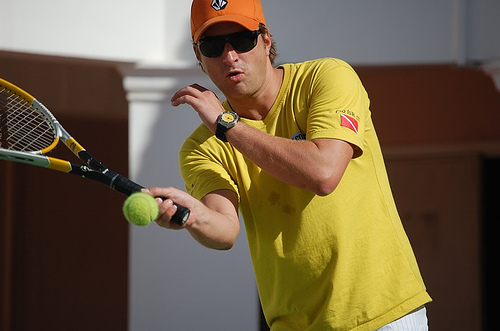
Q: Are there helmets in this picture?
A: No, there are no helmets.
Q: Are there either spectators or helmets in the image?
A: No, there are no helmets or spectators.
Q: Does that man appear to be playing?
A: Yes, the man is playing.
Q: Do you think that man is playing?
A: Yes, the man is playing.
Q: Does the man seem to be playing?
A: Yes, the man is playing.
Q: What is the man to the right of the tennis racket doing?
A: The man is playing.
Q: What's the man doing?
A: The man is playing.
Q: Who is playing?
A: The man is playing.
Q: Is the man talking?
A: No, the man is playing.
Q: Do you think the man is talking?
A: No, the man is playing.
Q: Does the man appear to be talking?
A: No, the man is playing.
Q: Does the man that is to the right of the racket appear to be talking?
A: No, the man is playing.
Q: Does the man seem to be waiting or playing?
A: The man is playing.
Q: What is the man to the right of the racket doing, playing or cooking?
A: The man is playing.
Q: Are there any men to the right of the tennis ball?
A: Yes, there is a man to the right of the tennis ball.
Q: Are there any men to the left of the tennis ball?
A: No, the man is to the right of the tennis ball.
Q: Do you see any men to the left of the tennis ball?
A: No, the man is to the right of the tennis ball.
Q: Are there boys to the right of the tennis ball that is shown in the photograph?
A: No, there is a man to the right of the tennis ball.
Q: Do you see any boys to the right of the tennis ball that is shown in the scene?
A: No, there is a man to the right of the tennis ball.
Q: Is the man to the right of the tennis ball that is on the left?
A: Yes, the man is to the right of the tennis ball.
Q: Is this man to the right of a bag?
A: No, the man is to the right of the tennis ball.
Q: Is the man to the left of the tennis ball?
A: No, the man is to the right of the tennis ball.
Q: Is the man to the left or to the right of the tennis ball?
A: The man is to the right of the tennis ball.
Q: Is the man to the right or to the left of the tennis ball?
A: The man is to the right of the tennis ball.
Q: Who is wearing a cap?
A: The man is wearing a cap.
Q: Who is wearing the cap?
A: The man is wearing a cap.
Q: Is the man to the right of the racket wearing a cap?
A: Yes, the man is wearing a cap.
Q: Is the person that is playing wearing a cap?
A: Yes, the man is wearing a cap.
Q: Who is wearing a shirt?
A: The man is wearing a shirt.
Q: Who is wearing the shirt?
A: The man is wearing a shirt.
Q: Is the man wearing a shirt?
A: Yes, the man is wearing a shirt.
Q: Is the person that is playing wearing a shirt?
A: Yes, the man is wearing a shirt.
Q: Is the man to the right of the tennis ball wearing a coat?
A: No, the man is wearing a shirt.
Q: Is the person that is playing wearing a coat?
A: No, the man is wearing a shirt.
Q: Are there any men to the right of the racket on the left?
A: Yes, there is a man to the right of the racket.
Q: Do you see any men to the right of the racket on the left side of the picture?
A: Yes, there is a man to the right of the racket.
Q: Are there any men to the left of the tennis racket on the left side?
A: No, the man is to the right of the tennis racket.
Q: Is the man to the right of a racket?
A: Yes, the man is to the right of a racket.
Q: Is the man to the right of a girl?
A: No, the man is to the right of a racket.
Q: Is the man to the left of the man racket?
A: No, the man is to the right of the tennis racket.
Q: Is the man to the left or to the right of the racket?
A: The man is to the right of the racket.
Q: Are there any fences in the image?
A: No, there are no fences.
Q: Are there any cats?
A: No, there are no cats.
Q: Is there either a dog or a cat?
A: No, there are no cats or dogs.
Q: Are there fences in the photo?
A: No, there are no fences.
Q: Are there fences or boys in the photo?
A: No, there are no fences or boys.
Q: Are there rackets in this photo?
A: Yes, there is a racket.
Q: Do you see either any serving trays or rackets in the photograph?
A: Yes, there is a racket.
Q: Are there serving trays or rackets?
A: Yes, there is a racket.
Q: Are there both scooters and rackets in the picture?
A: No, there is a racket but no scooters.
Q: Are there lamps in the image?
A: No, there are no lamps.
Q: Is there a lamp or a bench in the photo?
A: No, there are no lamps or benches.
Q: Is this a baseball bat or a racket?
A: This is a racket.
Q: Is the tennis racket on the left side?
A: Yes, the tennis racket is on the left of the image.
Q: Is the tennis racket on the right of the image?
A: No, the tennis racket is on the left of the image.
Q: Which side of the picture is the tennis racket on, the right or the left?
A: The tennis racket is on the left of the image.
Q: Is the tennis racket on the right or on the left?
A: The tennis racket is on the left of the image.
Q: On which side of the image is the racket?
A: The racket is on the left of the image.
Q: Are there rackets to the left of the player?
A: Yes, there is a racket to the left of the player.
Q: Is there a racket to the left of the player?
A: Yes, there is a racket to the left of the player.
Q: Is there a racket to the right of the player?
A: No, the racket is to the left of the player.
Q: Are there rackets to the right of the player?
A: No, the racket is to the left of the player.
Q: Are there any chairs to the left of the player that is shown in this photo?
A: No, there is a racket to the left of the player.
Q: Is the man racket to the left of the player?
A: Yes, the racket is to the left of the player.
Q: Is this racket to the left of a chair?
A: No, the racket is to the left of the player.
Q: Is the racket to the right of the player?
A: No, the racket is to the left of the player.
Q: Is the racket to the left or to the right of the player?
A: The racket is to the left of the player.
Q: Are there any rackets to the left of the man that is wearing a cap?
A: Yes, there is a racket to the left of the man.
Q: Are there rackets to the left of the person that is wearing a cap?
A: Yes, there is a racket to the left of the man.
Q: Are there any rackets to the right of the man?
A: No, the racket is to the left of the man.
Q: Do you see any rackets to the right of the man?
A: No, the racket is to the left of the man.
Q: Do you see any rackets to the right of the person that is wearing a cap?
A: No, the racket is to the left of the man.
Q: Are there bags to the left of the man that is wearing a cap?
A: No, there is a racket to the left of the man.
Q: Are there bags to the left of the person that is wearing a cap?
A: No, there is a racket to the left of the man.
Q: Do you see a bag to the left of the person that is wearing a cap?
A: No, there is a racket to the left of the man.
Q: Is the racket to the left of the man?
A: Yes, the racket is to the left of the man.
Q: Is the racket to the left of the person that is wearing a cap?
A: Yes, the racket is to the left of the man.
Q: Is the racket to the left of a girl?
A: No, the racket is to the left of the man.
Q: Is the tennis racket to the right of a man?
A: No, the tennis racket is to the left of a man.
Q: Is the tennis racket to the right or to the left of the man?
A: The tennis racket is to the left of the man.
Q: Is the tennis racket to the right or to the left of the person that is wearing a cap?
A: The tennis racket is to the left of the man.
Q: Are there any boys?
A: No, there are no boys.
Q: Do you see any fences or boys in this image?
A: No, there are no boys or fences.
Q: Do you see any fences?
A: No, there are no fences.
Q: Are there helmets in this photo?
A: No, there are no helmets.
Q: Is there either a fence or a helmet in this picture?
A: No, there are no helmets or fences.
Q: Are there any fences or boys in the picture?
A: No, there are no fences or boys.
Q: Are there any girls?
A: No, there are no girls.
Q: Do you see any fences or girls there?
A: No, there are no girls or fences.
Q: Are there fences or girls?
A: No, there are no girls or fences.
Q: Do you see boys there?
A: No, there are no boys.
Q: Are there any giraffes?
A: No, there are no giraffes.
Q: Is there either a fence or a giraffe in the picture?
A: No, there are no giraffes or fences.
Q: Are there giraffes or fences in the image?
A: No, there are no giraffes or fences.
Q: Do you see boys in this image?
A: No, there are no boys.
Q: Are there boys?
A: No, there are no boys.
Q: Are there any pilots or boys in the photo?
A: No, there are no boys or pilots.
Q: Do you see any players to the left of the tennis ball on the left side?
A: No, the player is to the right of the tennis ball.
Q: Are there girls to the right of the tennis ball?
A: No, there is a player to the right of the tennis ball.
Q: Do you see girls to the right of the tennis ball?
A: No, there is a player to the right of the tennis ball.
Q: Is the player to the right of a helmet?
A: No, the player is to the right of the tennis ball.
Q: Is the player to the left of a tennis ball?
A: No, the player is to the right of a tennis ball.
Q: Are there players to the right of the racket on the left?
A: Yes, there is a player to the right of the tennis racket.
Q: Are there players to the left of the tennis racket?
A: No, the player is to the right of the tennis racket.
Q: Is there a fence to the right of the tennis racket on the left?
A: No, there is a player to the right of the tennis racket.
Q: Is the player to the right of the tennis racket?
A: Yes, the player is to the right of the tennis racket.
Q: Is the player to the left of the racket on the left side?
A: No, the player is to the right of the tennis racket.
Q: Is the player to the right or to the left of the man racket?
A: The player is to the right of the racket.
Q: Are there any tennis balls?
A: Yes, there is a tennis ball.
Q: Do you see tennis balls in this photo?
A: Yes, there is a tennis ball.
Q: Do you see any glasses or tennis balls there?
A: Yes, there is a tennis ball.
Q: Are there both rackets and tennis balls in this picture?
A: Yes, there are both a tennis ball and a racket.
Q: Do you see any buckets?
A: No, there are no buckets.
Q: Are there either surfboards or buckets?
A: No, there are no buckets or surfboards.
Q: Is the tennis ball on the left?
A: Yes, the tennis ball is on the left of the image.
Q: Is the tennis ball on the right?
A: No, the tennis ball is on the left of the image.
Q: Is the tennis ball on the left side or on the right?
A: The tennis ball is on the left of the image.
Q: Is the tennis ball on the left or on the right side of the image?
A: The tennis ball is on the left of the image.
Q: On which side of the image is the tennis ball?
A: The tennis ball is on the left of the image.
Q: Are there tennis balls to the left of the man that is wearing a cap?
A: Yes, there is a tennis ball to the left of the man.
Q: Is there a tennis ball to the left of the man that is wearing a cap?
A: Yes, there is a tennis ball to the left of the man.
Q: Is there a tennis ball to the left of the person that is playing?
A: Yes, there is a tennis ball to the left of the man.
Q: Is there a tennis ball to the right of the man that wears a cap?
A: No, the tennis ball is to the left of the man.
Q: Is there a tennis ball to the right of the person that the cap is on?
A: No, the tennis ball is to the left of the man.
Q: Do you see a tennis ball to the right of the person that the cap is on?
A: No, the tennis ball is to the left of the man.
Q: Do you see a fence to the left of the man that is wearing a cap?
A: No, there is a tennis ball to the left of the man.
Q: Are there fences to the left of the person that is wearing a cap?
A: No, there is a tennis ball to the left of the man.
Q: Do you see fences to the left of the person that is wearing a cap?
A: No, there is a tennis ball to the left of the man.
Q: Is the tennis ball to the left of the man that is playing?
A: Yes, the tennis ball is to the left of the man.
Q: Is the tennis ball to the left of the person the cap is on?
A: Yes, the tennis ball is to the left of the man.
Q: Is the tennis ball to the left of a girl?
A: No, the tennis ball is to the left of the man.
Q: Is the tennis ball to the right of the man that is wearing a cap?
A: No, the tennis ball is to the left of the man.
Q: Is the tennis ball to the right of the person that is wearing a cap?
A: No, the tennis ball is to the left of the man.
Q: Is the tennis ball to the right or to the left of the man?
A: The tennis ball is to the left of the man.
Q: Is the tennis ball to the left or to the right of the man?
A: The tennis ball is to the left of the man.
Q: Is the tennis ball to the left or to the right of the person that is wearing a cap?
A: The tennis ball is to the left of the man.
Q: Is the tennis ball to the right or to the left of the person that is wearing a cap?
A: The tennis ball is to the left of the man.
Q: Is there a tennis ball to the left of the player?
A: Yes, there is a tennis ball to the left of the player.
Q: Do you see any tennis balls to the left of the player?
A: Yes, there is a tennis ball to the left of the player.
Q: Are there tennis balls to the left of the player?
A: Yes, there is a tennis ball to the left of the player.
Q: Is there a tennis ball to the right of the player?
A: No, the tennis ball is to the left of the player.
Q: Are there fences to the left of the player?
A: No, there is a tennis ball to the left of the player.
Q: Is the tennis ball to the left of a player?
A: Yes, the tennis ball is to the left of a player.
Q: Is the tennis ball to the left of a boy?
A: No, the tennis ball is to the left of a player.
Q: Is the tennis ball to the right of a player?
A: No, the tennis ball is to the left of a player.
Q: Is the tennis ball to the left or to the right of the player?
A: The tennis ball is to the left of the player.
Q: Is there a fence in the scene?
A: No, there are no fences.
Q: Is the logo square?
A: Yes, the logo is square.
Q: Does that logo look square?
A: Yes, the logo is square.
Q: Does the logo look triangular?
A: No, the logo is square.